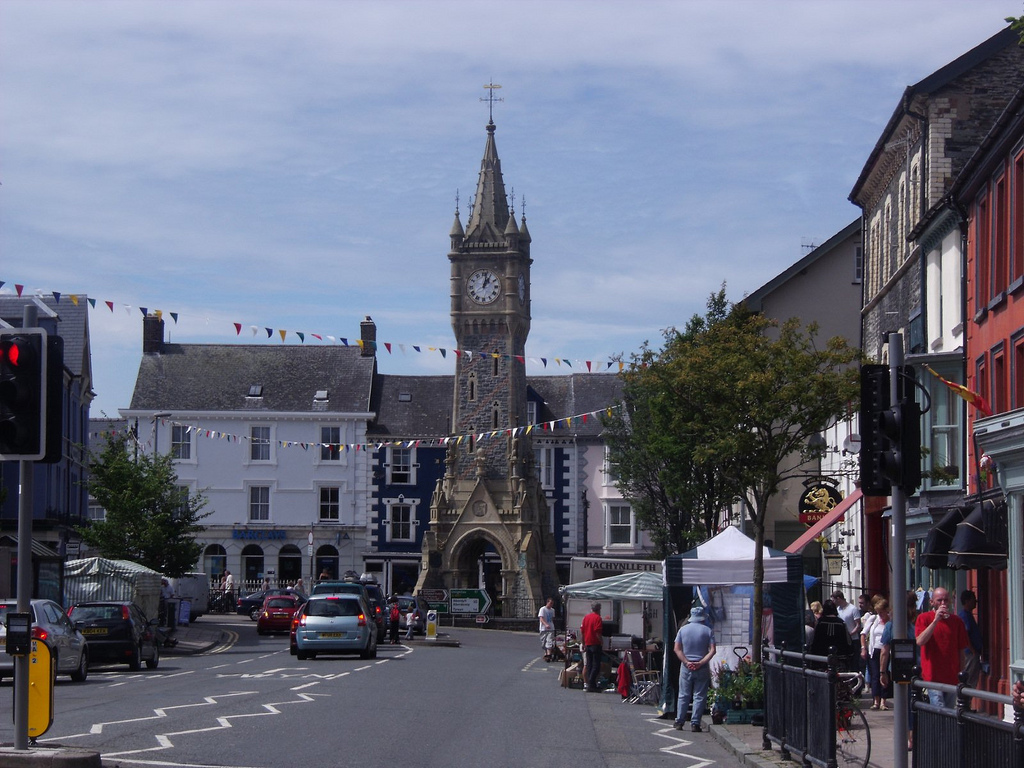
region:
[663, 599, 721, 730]
man with blue hat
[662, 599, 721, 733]
man with blue shirt and pants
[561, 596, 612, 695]
man with red shirt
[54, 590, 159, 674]
a dark blue station wagon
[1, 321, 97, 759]
a red traffic light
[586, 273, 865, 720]
a small green tree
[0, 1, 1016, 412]
blue and white sky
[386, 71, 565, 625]
tall monument with clock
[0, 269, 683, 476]
colorful banners hanging above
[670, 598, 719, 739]
a man with back turned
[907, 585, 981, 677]
a man drinking in red shirt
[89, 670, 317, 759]
white swiggy lines on road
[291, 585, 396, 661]
the back of a car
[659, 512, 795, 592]
the top of a tent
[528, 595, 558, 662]
a man in white pulling something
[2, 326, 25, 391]
a red light on sign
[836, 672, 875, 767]
a bike parked behind fence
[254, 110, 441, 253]
a sky that is blue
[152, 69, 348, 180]
clouds that are wispy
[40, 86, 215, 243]
a cloud that is big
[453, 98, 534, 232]
a roof that is very pointy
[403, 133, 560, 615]
a brown colored clock tower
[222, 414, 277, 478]
a window that is rectangular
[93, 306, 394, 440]
a roof that is very brown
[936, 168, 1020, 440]
a building that is red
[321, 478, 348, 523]
A window on a building.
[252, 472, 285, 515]
A window on a building.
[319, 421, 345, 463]
A window on a building.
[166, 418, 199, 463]
A window on a building.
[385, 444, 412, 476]
A window on a building.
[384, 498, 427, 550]
A window on a building.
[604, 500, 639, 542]
A window on a building.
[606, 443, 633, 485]
A window on a building.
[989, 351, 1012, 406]
A window on a building.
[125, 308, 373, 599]
a tall white building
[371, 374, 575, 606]
A white and blue building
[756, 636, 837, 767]
a black metal railing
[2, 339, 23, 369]
A traffic light signal is red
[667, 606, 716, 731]
a man with his arms behind his back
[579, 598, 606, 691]
a man wearing a red shirt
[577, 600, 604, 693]
a man wearing black pants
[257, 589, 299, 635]
a red car being driven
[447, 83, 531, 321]
white clock on grey tower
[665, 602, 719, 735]
man in blue shirt standing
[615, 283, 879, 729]
green tree over white and blue tent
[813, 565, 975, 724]
group of people standing in front of store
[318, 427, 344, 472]
A window on a building.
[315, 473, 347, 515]
A window on a building.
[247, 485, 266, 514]
A window on a building.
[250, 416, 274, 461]
A window on a building.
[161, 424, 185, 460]
A window on a building.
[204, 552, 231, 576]
A window on a building.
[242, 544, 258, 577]
A window on a building.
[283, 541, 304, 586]
A window on a building.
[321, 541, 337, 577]
A window on a building.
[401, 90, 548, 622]
large clock tower with pointed spires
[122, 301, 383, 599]
white building with arched entryways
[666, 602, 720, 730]
man wearing blue jeans and a hat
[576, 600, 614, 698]
man wearing a red shirt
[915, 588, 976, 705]
man wearing a red shirt